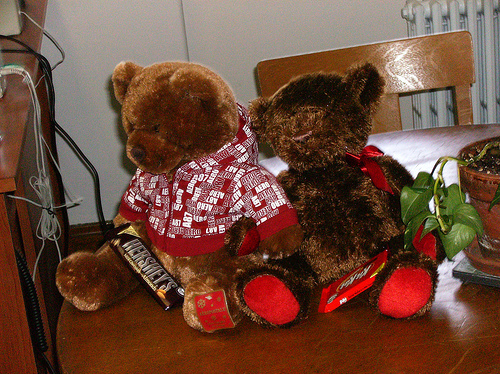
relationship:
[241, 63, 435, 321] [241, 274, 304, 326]
bear has pads